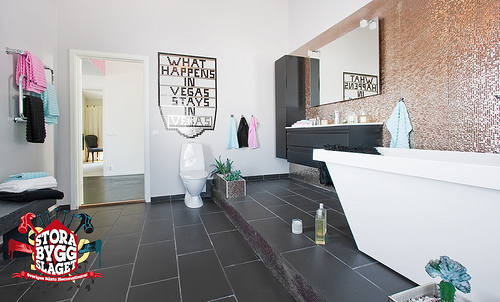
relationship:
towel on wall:
[387, 101, 412, 143] [296, 32, 500, 144]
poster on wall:
[159, 54, 215, 132] [60, 7, 278, 182]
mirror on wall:
[308, 36, 383, 102] [296, 32, 500, 144]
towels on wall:
[226, 111, 263, 149] [60, 7, 278, 182]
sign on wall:
[159, 54, 215, 132] [60, 7, 278, 182]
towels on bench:
[6, 173, 57, 202] [0, 194, 65, 241]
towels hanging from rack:
[16, 54, 55, 125] [5, 44, 68, 143]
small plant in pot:
[208, 162, 237, 173] [222, 176, 245, 193]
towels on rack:
[16, 54, 55, 125] [5, 44, 68, 143]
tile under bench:
[26, 192, 368, 300] [0, 194, 65, 241]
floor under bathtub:
[26, 192, 368, 300] [316, 139, 500, 281]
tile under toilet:
[26, 192, 368, 300] [181, 145, 207, 204]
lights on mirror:
[360, 17, 370, 27] [308, 36, 383, 102]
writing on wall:
[159, 54, 215, 132] [60, 7, 278, 182]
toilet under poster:
[181, 145, 207, 204] [159, 54, 215, 132]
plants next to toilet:
[203, 156, 252, 194] [181, 145, 207, 204]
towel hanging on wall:
[227, 117, 239, 149] [60, 7, 278, 182]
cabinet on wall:
[277, 129, 375, 164] [296, 32, 500, 144]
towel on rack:
[26, 98, 43, 139] [5, 44, 68, 143]